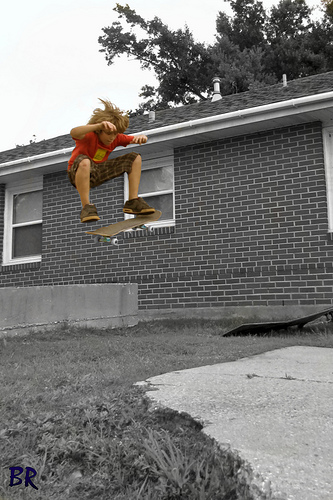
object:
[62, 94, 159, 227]
boy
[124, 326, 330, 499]
cement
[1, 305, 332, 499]
grass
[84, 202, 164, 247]
skateboard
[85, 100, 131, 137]
hair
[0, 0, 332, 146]
air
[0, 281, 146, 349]
wall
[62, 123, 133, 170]
shirt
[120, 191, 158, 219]
shoe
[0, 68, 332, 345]
house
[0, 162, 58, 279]
window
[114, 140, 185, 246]
window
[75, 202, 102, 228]
right foot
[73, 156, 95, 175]
right knee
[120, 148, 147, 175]
left knee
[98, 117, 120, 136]
right hand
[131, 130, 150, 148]
left hand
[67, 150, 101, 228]
right leg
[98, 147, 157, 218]
left leg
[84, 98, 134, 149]
head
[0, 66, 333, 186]
roof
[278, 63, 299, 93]
vent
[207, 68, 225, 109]
vent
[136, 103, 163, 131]
vent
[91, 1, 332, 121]
tree